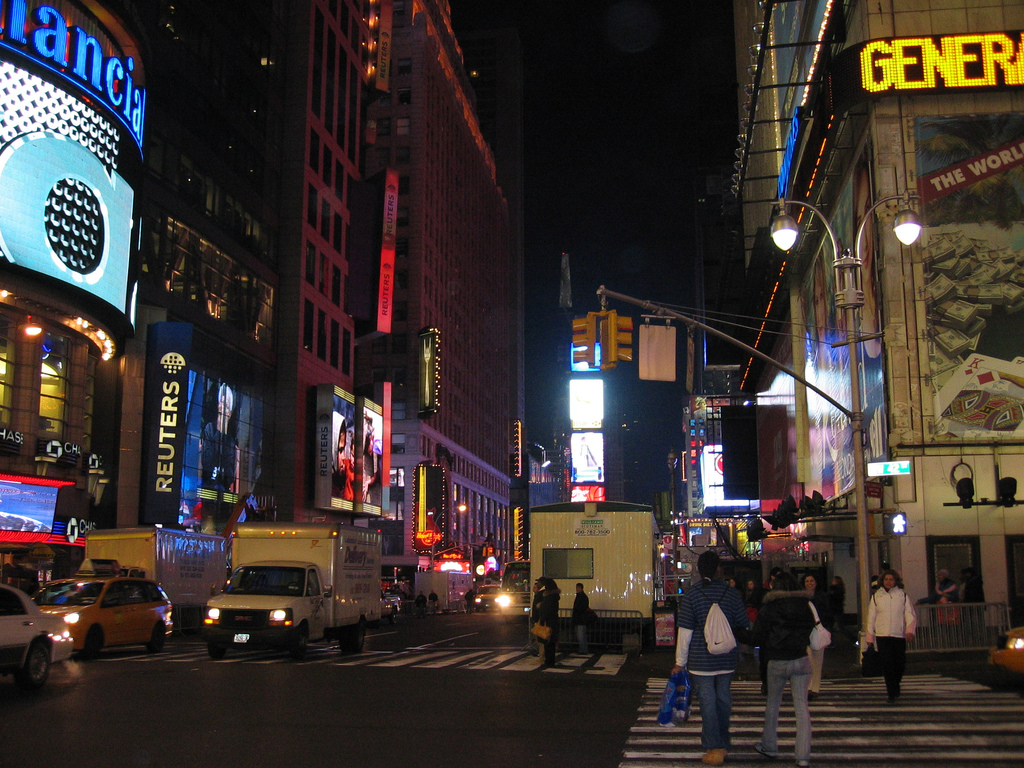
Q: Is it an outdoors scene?
A: Yes, it is outdoors.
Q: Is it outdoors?
A: Yes, it is outdoors.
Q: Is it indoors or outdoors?
A: It is outdoors.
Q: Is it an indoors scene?
A: No, it is outdoors.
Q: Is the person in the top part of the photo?
A: No, the person is in the bottom of the image.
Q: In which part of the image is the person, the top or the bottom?
A: The person is in the bottom of the image.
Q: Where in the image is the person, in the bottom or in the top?
A: The person is in the bottom of the image.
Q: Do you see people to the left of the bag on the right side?
A: Yes, there is a person to the left of the bag.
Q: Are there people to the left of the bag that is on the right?
A: Yes, there is a person to the left of the bag.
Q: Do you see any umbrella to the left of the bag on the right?
A: No, there is a person to the left of the bag.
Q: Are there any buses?
A: No, there are no buses.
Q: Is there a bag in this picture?
A: Yes, there is a bag.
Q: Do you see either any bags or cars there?
A: Yes, there is a bag.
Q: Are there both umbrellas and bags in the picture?
A: No, there is a bag but no umbrellas.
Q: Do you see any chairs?
A: No, there are no chairs.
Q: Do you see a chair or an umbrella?
A: No, there are no chairs or umbrellas.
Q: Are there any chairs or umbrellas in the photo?
A: No, there are no chairs or umbrellas.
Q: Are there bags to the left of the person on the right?
A: Yes, there is a bag to the left of the person.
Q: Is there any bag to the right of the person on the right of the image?
A: No, the bag is to the left of the person.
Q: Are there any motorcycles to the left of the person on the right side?
A: No, there is a bag to the left of the person.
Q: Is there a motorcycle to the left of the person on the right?
A: No, there is a bag to the left of the person.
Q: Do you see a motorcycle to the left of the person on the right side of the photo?
A: No, there is a bag to the left of the person.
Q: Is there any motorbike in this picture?
A: No, there are no motorcycles.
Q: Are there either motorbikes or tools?
A: No, there are no motorbikes or tools.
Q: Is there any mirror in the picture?
A: No, there are no mirrors.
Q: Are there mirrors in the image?
A: No, there are no mirrors.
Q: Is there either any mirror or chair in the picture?
A: No, there are no mirrors or chairs.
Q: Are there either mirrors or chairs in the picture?
A: No, there are no mirrors or chairs.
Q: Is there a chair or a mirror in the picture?
A: No, there are no mirrors or chairs.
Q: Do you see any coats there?
A: Yes, there is a coat.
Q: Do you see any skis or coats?
A: Yes, there is a coat.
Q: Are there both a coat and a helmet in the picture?
A: No, there is a coat but no helmets.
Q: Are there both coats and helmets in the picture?
A: No, there is a coat but no helmets.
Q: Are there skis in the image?
A: No, there are no skis.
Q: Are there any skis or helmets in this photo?
A: No, there are no skis or helmets.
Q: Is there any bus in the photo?
A: No, there are no buses.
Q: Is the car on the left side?
A: Yes, the car is on the left of the image.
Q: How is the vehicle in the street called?
A: The vehicle is a car.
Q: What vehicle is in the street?
A: The vehicle is a car.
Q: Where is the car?
A: The car is in the street.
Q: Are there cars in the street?
A: Yes, there is a car in the street.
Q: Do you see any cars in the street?
A: Yes, there is a car in the street.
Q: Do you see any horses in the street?
A: No, there is a car in the street.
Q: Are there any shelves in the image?
A: No, there are no shelves.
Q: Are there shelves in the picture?
A: No, there are no shelves.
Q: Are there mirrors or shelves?
A: No, there are no shelves or mirrors.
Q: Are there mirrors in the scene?
A: No, there are no mirrors.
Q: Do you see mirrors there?
A: No, there are no mirrors.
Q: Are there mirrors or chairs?
A: No, there are no mirrors or chairs.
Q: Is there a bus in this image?
A: No, there are no buses.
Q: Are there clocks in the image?
A: No, there are no clocks.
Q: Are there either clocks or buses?
A: No, there are no clocks or buses.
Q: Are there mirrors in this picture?
A: No, there are no mirrors.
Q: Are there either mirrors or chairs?
A: No, there are no mirrors or chairs.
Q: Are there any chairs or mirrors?
A: No, there are no mirrors or chairs.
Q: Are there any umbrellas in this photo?
A: No, there are no umbrellas.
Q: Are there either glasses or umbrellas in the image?
A: No, there are no umbrellas or glasses.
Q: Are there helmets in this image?
A: No, there are no helmets.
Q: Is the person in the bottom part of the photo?
A: Yes, the person is in the bottom of the image.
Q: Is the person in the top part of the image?
A: No, the person is in the bottom of the image.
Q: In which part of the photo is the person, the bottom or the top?
A: The person is in the bottom of the image.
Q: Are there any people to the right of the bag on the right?
A: Yes, there is a person to the right of the bag.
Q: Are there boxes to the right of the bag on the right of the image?
A: No, there is a person to the right of the bag.